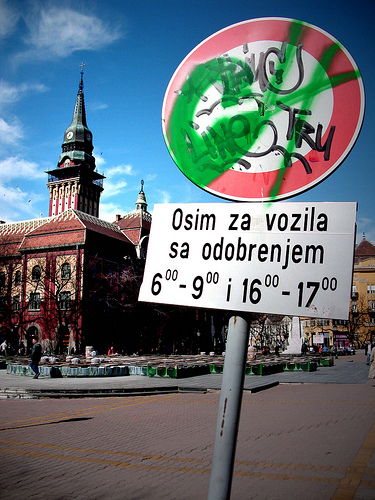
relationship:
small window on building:
[62, 262, 72, 280] [0, 207, 138, 354]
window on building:
[56, 290, 72, 310] [7, 49, 211, 414]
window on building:
[26, 261, 44, 281] [0, 70, 148, 370]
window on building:
[40, 306, 83, 362] [11, 209, 135, 371]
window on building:
[365, 282, 373, 294] [301, 228, 373, 350]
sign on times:
[137, 200, 359, 322] [134, 260, 345, 309]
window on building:
[61, 261, 69, 278] [0, 53, 219, 365]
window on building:
[56, 291, 70, 310] [0, 53, 219, 365]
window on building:
[31, 263, 41, 282] [0, 53, 219, 365]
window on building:
[28, 290, 43, 313] [0, 53, 219, 365]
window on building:
[12, 293, 20, 312] [0, 53, 219, 365]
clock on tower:
[62, 129, 73, 141] [42, 60, 104, 216]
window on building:
[28, 290, 43, 313] [0, 153, 174, 360]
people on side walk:
[19, 322, 47, 386] [2, 365, 206, 407]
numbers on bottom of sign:
[150, 269, 337, 306] [137, 200, 359, 322]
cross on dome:
[71, 60, 94, 83] [60, 49, 97, 153]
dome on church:
[60, 49, 97, 153] [13, 42, 183, 350]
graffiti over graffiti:
[175, 60, 294, 153] [164, 16, 361, 211]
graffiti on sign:
[175, 60, 294, 153] [161, 16, 365, 202]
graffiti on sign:
[164, 16, 361, 211] [161, 16, 365, 202]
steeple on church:
[44, 61, 107, 216] [0, 61, 228, 356]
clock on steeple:
[67, 131, 74, 140] [44, 61, 107, 216]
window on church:
[31, 263, 41, 282] [6, 56, 137, 352]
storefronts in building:
[295, 317, 371, 367] [0, 57, 150, 373]